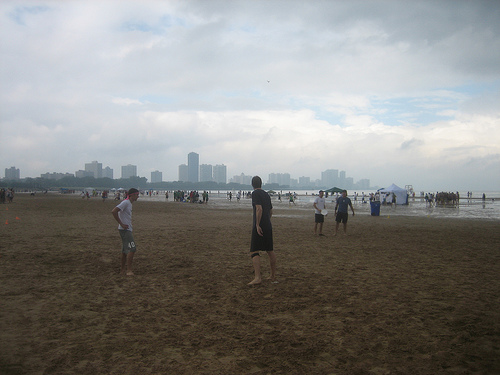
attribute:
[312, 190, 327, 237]
man — light skinned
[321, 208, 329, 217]
plate — white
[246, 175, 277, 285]
man — wearing all black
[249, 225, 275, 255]
shorts — black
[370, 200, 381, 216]
bin — blue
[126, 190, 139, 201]
ribbon — orange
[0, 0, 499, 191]
sky — gray, cloudy, overcast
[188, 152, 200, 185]
building — tall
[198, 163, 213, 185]
building — tall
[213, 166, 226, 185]
building — tall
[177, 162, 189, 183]
building — tall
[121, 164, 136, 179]
building — tall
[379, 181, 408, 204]
tent — white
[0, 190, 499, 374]
sand — brown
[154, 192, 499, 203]
water — gray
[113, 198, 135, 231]
shirt — white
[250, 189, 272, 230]
shirt — dark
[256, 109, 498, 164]
cloud — grey